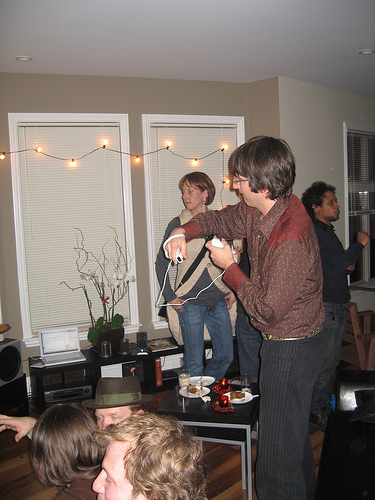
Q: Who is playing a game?
A: A man.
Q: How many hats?
A: One.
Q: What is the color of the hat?
A: Brown and green.